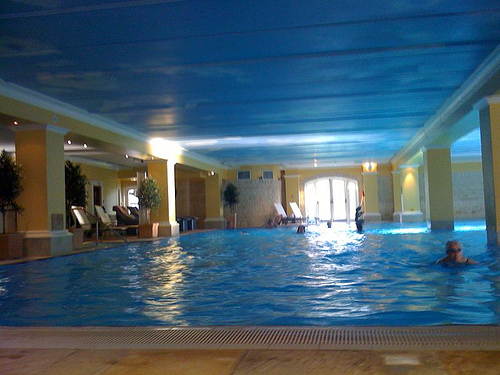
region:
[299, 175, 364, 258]
Sunshine shining through a large window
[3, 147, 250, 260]
Potted trees lining the side of a swimming pool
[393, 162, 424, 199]
Lighted light fixture on wall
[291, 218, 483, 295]
People swimming in a pool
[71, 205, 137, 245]
White lounge chairs on the side of a swimming pool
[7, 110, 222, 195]
Recessed lighting in ceiling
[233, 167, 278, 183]
Two white vents in wall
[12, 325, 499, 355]
Tread on swimming pool border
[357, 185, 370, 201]
Red item hanging on wall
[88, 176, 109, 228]
White trimmed doorway behind chair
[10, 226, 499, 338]
indoor pool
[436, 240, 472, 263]
woman swimming in the pool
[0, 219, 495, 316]
blue water in the pool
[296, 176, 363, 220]
doors on the back wall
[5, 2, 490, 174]
blue ceiling above the pool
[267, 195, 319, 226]
chairs beside the doors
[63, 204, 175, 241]
chairs on the left side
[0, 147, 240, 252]
plants next to yellow colums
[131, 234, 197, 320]
reflection of light on the water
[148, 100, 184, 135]
reflection of light on the ceiling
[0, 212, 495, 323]
Indoor swimming pool with blue water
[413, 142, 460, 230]
One of several neutral color pillars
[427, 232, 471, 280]
Older person swimming in the pool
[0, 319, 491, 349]
Edge of pool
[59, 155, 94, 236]
One of several fake trees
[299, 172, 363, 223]
Door to the outside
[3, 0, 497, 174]
Ceiling with reflection of swimming pool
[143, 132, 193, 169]
Bright light above the pool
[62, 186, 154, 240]
Chairs along the edge of the pool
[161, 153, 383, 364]
this is an indoor pool inside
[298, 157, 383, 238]
this is a window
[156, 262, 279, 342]
the water is very blue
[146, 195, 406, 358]
this is a large pool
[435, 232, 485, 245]
this is an elderly woman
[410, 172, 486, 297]
this is a woman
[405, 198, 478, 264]
these are some gogggles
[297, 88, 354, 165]
this is a ceiling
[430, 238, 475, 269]
A person in a pool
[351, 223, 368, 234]
A person in a pool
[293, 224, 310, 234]
A person in a pool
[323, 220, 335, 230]
A person in a pool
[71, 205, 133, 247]
some handrails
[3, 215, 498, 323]
A large pool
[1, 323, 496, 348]
A drain by the pool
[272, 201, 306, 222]
a large white chair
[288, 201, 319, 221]
a large white chair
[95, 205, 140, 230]
a large white chair